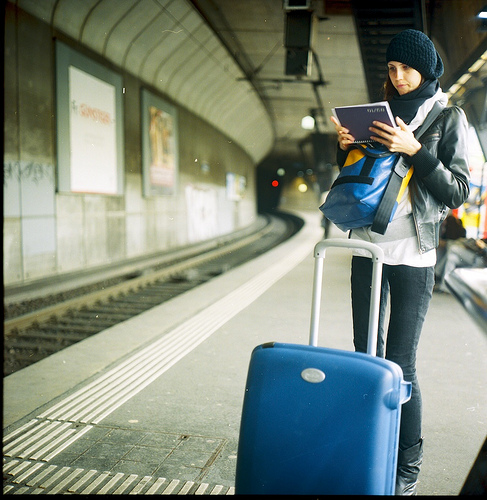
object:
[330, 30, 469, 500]
woman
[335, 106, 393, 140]
notebook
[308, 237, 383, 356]
travel case handle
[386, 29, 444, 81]
hat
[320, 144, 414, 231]
bag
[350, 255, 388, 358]
leg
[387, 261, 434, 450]
leg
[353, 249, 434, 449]
pants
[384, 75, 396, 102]
hair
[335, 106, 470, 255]
jacket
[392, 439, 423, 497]
boot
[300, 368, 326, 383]
label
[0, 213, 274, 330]
train tracks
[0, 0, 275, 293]
wall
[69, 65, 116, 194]
advertisement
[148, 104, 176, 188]
advertisement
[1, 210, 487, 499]
cement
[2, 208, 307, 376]
bumps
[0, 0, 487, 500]
train station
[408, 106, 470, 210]
womans arms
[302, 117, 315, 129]
lights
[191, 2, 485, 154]
ceiling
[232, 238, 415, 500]
suitcase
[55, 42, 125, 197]
advertisement panel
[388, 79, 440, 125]
scarf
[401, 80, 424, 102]
neck